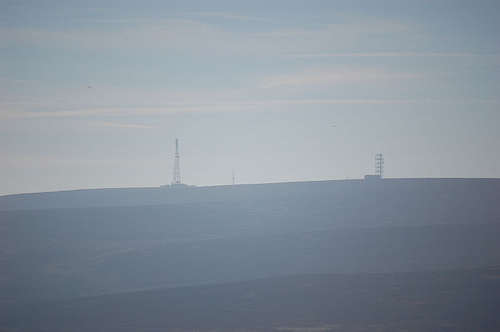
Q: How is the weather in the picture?
A: It is foggy.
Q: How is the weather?
A: It is foggy.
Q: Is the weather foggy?
A: Yes, it is foggy.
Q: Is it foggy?
A: Yes, it is foggy.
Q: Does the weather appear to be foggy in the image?
A: Yes, it is foggy.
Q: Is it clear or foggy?
A: It is foggy.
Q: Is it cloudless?
A: No, it is foggy.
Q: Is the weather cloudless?
A: No, it is foggy.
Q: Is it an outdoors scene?
A: Yes, it is outdoors.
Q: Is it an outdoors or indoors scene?
A: It is outdoors.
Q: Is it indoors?
A: No, it is outdoors.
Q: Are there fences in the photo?
A: No, there are no fences.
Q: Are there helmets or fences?
A: No, there are no fences or helmets.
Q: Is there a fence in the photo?
A: No, there are no fences.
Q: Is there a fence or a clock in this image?
A: No, there are no fences or clocks.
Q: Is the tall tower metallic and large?
A: Yes, the tower is metallic and large.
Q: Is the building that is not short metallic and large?
A: Yes, the tower is metallic and large.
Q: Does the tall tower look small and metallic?
A: No, the tower is metallic but large.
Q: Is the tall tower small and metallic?
A: No, the tower is metallic but large.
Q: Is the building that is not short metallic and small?
A: No, the tower is metallic but large.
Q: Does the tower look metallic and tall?
A: Yes, the tower is metallic and tall.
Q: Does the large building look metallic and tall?
A: Yes, the tower is metallic and tall.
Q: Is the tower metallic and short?
A: No, the tower is metallic but tall.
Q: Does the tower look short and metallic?
A: No, the tower is metallic but tall.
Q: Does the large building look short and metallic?
A: No, the tower is metallic but tall.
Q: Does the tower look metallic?
A: Yes, the tower is metallic.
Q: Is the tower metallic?
A: Yes, the tower is metallic.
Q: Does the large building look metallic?
A: Yes, the tower is metallic.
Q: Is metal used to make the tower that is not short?
A: Yes, the tower is made of metal.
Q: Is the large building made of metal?
A: Yes, the tower is made of metal.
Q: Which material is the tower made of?
A: The tower is made of metal.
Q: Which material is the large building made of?
A: The tower is made of metal.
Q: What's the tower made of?
A: The tower is made of metal.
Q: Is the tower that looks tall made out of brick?
A: No, the tower is made of metal.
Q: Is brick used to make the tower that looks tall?
A: No, the tower is made of metal.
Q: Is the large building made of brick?
A: No, the tower is made of metal.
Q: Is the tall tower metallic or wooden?
A: The tower is metallic.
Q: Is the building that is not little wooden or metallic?
A: The tower is metallic.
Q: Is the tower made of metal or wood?
A: The tower is made of metal.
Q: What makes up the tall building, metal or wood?
A: The tower is made of metal.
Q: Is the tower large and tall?
A: Yes, the tower is large and tall.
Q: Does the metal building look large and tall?
A: Yes, the tower is large and tall.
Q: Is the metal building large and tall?
A: Yes, the tower is large and tall.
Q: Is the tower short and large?
A: No, the tower is large but tall.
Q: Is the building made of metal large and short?
A: No, the tower is large but tall.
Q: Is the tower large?
A: Yes, the tower is large.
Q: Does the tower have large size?
A: Yes, the tower is large.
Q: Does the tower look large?
A: Yes, the tower is large.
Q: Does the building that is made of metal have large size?
A: Yes, the tower is large.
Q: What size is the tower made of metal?
A: The tower is large.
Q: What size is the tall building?
A: The tower is large.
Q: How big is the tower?
A: The tower is large.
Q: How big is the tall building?
A: The tower is large.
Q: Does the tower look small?
A: No, the tower is large.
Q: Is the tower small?
A: No, the tower is large.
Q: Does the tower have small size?
A: No, the tower is large.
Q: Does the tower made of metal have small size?
A: No, the tower is large.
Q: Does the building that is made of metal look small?
A: No, the tower is large.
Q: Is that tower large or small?
A: The tower is large.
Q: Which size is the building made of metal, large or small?
A: The tower is large.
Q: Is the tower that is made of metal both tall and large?
A: Yes, the tower is tall and large.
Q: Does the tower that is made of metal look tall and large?
A: Yes, the tower is tall and large.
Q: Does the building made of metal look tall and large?
A: Yes, the tower is tall and large.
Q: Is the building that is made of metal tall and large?
A: Yes, the tower is tall and large.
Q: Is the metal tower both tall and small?
A: No, the tower is tall but large.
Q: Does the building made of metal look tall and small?
A: No, the tower is tall but large.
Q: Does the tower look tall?
A: Yes, the tower is tall.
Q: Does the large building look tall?
A: Yes, the tower is tall.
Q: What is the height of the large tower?
A: The tower is tall.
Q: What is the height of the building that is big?
A: The tower is tall.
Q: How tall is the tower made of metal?
A: The tower is tall.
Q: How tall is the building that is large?
A: The tower is tall.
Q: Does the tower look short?
A: No, the tower is tall.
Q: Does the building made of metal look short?
A: No, the tower is tall.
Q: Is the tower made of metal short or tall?
A: The tower is tall.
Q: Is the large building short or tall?
A: The tower is tall.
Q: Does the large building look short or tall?
A: The tower is tall.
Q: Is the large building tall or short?
A: The tower is tall.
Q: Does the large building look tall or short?
A: The tower is tall.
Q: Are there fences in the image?
A: No, there are no fences.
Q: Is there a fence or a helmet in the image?
A: No, there are no fences or helmets.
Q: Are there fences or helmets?
A: No, there are no fences or helmets.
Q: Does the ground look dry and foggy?
A: Yes, the ground is dry and foggy.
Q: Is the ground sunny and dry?
A: No, the ground is dry but foggy.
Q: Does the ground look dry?
A: Yes, the ground is dry.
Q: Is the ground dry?
A: Yes, the ground is dry.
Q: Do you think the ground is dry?
A: Yes, the ground is dry.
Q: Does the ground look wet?
A: No, the ground is dry.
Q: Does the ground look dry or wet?
A: The ground is dry.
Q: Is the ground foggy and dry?
A: Yes, the ground is foggy and dry.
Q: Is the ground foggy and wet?
A: No, the ground is foggy but dry.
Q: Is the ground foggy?
A: Yes, the ground is foggy.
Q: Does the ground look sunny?
A: No, the ground is foggy.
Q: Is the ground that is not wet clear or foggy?
A: The ground is foggy.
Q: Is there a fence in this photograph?
A: No, there are no fences.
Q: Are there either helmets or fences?
A: No, there are no fences or helmets.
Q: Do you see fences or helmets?
A: No, there are no fences or helmets.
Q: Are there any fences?
A: No, there are no fences.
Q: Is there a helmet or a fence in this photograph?
A: No, there are no fences or helmets.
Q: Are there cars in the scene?
A: No, there are no cars.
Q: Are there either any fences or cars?
A: No, there are no cars or fences.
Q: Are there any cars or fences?
A: No, there are no cars or fences.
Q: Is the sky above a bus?
A: No, the sky is above the tower.